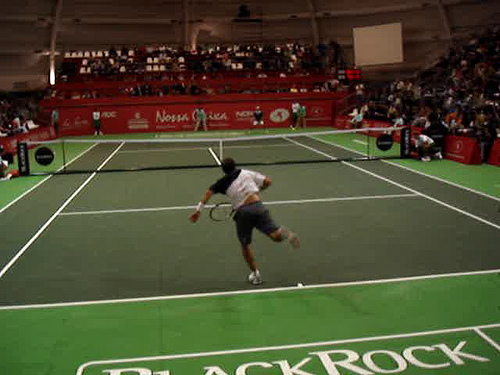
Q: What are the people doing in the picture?
A: Playing tennis.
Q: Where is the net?
A: Middle of the court.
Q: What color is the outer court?
A: Green.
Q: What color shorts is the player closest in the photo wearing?
A: Grey.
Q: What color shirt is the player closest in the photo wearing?
A: Black and white.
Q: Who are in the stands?
A: Spectators.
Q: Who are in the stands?
A: Fans.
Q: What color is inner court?
A: Grey.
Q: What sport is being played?
A: Tennis.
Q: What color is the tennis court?
A: Green.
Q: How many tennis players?
A: Two.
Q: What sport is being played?
A: Tennis.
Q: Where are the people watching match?
A: In the bleachers.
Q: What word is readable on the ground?
A: Rock.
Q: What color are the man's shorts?
A: Gray.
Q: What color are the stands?
A: Red.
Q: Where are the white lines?
A: On tennis court.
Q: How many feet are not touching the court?
A: One.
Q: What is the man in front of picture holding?
A: Tennis racket.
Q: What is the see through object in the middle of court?
A: Net.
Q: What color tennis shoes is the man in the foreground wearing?
A: White.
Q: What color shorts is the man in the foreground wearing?
A: Grey.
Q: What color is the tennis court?
A: Green.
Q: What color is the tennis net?
A: Black and white.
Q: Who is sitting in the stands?
A: Crowd.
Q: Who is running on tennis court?
A: Man in white shirt.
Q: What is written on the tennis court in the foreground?
A: BlackRock.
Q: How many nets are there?
A: One.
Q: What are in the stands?
A: Spectators.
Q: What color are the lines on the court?
A: White.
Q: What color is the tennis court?
A: Green.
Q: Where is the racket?
A: In the player's hand.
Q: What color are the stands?
A: Red.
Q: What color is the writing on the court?
A: White.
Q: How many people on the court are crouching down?
A: One.